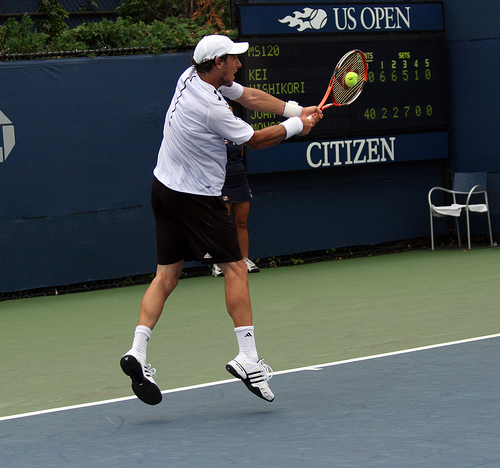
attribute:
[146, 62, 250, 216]
shirt — white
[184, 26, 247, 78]
cap — white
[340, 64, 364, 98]
ball — green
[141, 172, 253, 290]
shorts — black, blakc